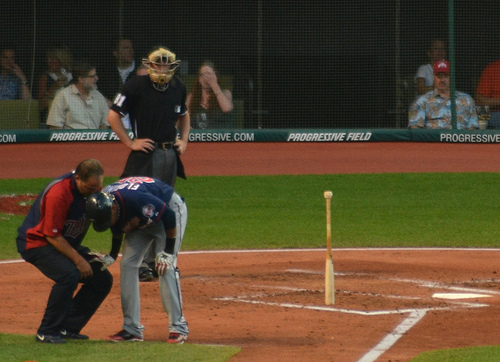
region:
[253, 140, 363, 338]
This is a baseball bat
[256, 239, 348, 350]
This is a baseball diamond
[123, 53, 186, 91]
This is a helmet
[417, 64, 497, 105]
This is a man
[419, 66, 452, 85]
This is a hat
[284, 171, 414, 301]
This is very short grass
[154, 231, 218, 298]
This is a glove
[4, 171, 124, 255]
This is a picture of a polo shirt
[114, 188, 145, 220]
The shirt is blue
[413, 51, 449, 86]
The hat is red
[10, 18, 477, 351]
photo taken at a baseball field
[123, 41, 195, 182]
baseball umpire with hands on his hips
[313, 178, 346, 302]
wooden baseball bat standing by itself in batter's box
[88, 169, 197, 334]
baseball player hunched over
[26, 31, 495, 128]
spectators sitting in the stands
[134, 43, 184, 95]
protective gear over umpires face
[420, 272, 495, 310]
white home plate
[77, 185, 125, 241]
baseball player wearing blue batter's helmet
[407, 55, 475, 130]
fan wearing a hawaiian shirt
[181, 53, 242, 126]
woman with her hand over her face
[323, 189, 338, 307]
wooden baseball bat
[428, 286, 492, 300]
white home base on ground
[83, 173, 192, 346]
baseball player leaning over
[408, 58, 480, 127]
man in stands wearing red baseball cap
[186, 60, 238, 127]
lady behind net with hand over face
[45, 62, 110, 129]
man in stands wearing white dress shirt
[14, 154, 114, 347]
man squatting wearing red and blue shirt and black pants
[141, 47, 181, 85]
face mask of umpire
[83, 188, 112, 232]
black baseball helmet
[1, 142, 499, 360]
baseball field with brown dirt and green grass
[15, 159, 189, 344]
Man holding onto another man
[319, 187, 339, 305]
Baseball bat sticking straight up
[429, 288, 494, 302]
White base on a baseball field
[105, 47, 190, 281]
Man standing with his hands on hit hips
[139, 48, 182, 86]
Gold colored ump helmet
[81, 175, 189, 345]
Baseball player leaning over in pain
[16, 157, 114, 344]
Man bending down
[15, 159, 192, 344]
Man whispering to a baseball player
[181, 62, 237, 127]
Woman covering her face with her hand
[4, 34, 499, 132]
People watching a baseball game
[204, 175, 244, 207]
short green grass on baseball field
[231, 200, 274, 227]
short green grass on baseball field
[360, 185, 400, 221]
short green grass on baseball field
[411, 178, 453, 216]
short green grass on baseball field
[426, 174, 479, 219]
short green grass on baseball field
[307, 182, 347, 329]
brown wooden bat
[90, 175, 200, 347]
baseball player bent over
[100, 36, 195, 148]
baseball umpire druing game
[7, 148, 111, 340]
baseball trainer wearing uniform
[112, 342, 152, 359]
short green grass on baseball field